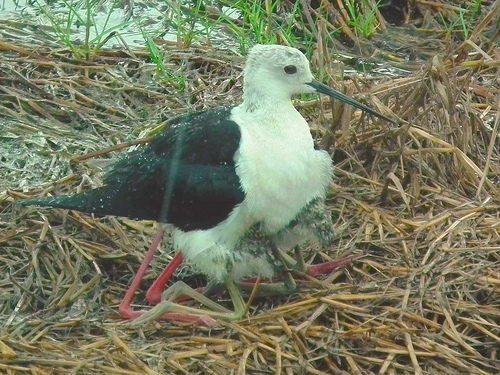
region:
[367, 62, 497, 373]
dried brown vegetation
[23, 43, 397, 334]
bird standing on dried grass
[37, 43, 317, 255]
bird with white chest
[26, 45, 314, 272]
black tail feathers on bird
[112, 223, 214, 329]
bent red bird legs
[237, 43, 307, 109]
black eye on bird head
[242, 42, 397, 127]
long pointy beak on bird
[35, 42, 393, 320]
side view of bird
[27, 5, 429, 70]
blades of green grass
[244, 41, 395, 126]
long dark bird beak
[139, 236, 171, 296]
The birds legs are red.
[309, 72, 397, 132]
The birds beak is black.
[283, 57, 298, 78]
The birds eye is black.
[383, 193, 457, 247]
The birds nest is brown.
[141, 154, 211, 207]
The birds wing is black.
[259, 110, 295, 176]
The birds chest is white.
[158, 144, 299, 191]
The bird is blakck and white.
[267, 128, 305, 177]
The bird has white feathers.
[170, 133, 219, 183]
The bird has black feathers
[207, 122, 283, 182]
The bird has fluffy white and black feathers.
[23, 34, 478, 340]
This is a bird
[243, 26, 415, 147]
Head of a bird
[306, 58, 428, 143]
Peak of a bird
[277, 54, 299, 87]
Eye of a bird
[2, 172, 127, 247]
Tail of a bird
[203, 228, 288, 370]
Legs of a bird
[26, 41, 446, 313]
This is a black and white bird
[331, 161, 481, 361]
This is dry grass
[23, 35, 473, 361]
A white bird relaxing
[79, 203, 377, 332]
THE BIRD HAS RED LEGS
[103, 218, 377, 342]
THE BIRD HAS LONG LEGS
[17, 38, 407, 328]
THE BIRD HAS BLACK AND WHITE FEATHERS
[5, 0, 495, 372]
THE BIRD IS IN BROWN GRASS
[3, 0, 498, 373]
THE GRASS IS DRY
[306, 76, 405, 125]
THE BIRD HAS A SHARP BEAK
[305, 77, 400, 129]
THE BIRD HAS A BLACK BEAK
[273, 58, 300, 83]
THE BIRD HAS A BLACK EYE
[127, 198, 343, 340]
THE BIRD HAS A BABY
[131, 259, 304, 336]
THE BABY HAS BROWN LEGS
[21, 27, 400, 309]
A weird little black and white bird.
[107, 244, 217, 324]
The little pink feet of the bird.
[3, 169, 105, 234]
The tail of the little bird.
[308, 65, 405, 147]
The long beck of the little bird.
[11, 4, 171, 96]
The grassy back ground behind the bird.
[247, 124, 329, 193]
The white feathers of the bird.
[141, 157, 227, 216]
The black feathers of the bird.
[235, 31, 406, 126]
The head of the little bird.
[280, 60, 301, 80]
The black eye of the little bird.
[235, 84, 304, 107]
The neck of the little bird.